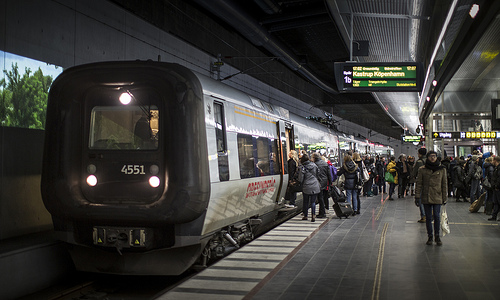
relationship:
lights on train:
[117, 89, 134, 108] [37, 55, 394, 280]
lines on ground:
[368, 222, 389, 299] [159, 191, 499, 296]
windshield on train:
[86, 104, 161, 152] [37, 55, 394, 280]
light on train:
[85, 172, 98, 185] [37, 55, 394, 280]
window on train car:
[88, 99, 163, 156] [374, 139, 398, 156]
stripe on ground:
[364, 216, 392, 296] [347, 235, 390, 295]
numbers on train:
[120, 164, 146, 175] [37, 55, 394, 280]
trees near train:
[0, 58, 49, 127] [47, 45, 344, 243]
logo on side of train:
[230, 179, 283, 205] [56, 63, 281, 253]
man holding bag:
[413, 150, 448, 247] [438, 203, 450, 238]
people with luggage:
[286, 140, 371, 227] [328, 184, 355, 215]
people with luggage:
[286, 140, 371, 227] [316, 165, 330, 192]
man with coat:
[413, 150, 448, 247] [413, 165, 448, 207]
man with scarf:
[413, 150, 448, 247] [422, 160, 442, 168]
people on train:
[286, 148, 396, 222] [47, 46, 349, 223]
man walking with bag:
[415, 149, 446, 248] [440, 203, 450, 234]